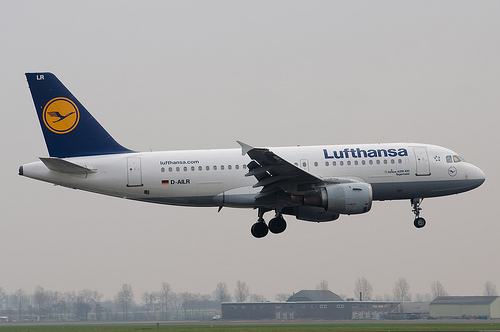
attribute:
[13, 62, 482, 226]
plane — white, flying, blue, big, leaving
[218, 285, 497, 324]
building — white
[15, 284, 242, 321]
trees — dark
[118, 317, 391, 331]
grass — green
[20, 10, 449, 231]
sky — white